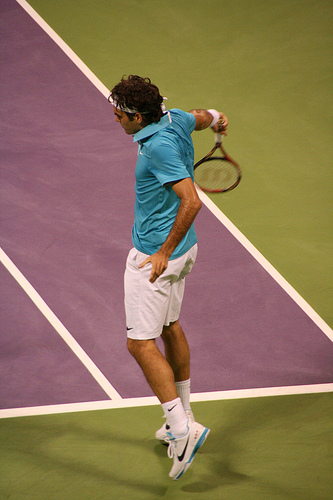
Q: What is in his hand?
A: A tennis racket.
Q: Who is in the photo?
A: A tennis player.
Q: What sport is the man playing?
A: Tennis.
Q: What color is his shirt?
A: Blue.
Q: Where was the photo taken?
A: A tennis court.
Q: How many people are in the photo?
A: One.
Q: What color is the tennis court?
A: Green and purple.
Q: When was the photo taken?
A: During the day.